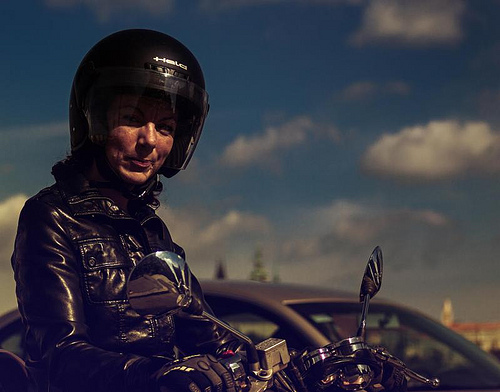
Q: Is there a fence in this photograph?
A: No, there are no fences.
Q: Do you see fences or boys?
A: No, there are no fences or boys.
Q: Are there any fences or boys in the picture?
A: No, there are no fences or boys.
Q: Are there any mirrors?
A: Yes, there is a mirror.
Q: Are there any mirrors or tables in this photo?
A: Yes, there is a mirror.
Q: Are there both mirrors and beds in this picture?
A: No, there is a mirror but no beds.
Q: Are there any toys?
A: No, there are no toys.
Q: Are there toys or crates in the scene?
A: No, there are no toys or crates.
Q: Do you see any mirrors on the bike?
A: Yes, there is a mirror on the bike.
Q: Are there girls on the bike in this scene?
A: No, there is a mirror on the bike.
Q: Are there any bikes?
A: Yes, there is a bike.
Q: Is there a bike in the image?
A: Yes, there is a bike.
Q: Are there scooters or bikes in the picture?
A: Yes, there is a bike.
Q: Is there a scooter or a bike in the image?
A: Yes, there is a bike.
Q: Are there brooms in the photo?
A: No, there are no brooms.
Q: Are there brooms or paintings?
A: No, there are no brooms or paintings.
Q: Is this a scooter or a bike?
A: This is a bike.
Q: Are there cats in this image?
A: No, there are no cats.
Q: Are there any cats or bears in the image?
A: No, there are no cats or bears.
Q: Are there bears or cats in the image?
A: No, there are no cats or bears.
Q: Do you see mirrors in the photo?
A: Yes, there is a mirror.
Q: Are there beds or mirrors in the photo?
A: Yes, there is a mirror.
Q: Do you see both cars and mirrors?
A: Yes, there are both a mirror and a car.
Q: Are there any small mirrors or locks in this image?
A: Yes, there is a small mirror.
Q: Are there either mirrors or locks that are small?
A: Yes, the mirror is small.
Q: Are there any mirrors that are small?
A: Yes, there is a small mirror.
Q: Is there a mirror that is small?
A: Yes, there is a mirror that is small.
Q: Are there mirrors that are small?
A: Yes, there is a mirror that is small.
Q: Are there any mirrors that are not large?
A: Yes, there is a small mirror.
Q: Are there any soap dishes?
A: No, there are no soap dishes.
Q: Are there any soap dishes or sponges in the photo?
A: No, there are no soap dishes or sponges.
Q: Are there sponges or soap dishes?
A: No, there are no soap dishes or sponges.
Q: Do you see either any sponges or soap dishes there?
A: No, there are no soap dishes or sponges.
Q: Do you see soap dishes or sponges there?
A: No, there are no soap dishes or sponges.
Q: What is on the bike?
A: The mirror is on the bike.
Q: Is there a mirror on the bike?
A: Yes, there is a mirror on the bike.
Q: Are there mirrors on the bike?
A: Yes, there is a mirror on the bike.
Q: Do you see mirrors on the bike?
A: Yes, there is a mirror on the bike.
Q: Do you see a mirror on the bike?
A: Yes, there is a mirror on the bike.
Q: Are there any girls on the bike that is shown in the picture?
A: No, there is a mirror on the bike.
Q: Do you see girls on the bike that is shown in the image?
A: No, there is a mirror on the bike.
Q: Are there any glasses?
A: No, there are no glasses.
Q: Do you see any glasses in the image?
A: No, there are no glasses.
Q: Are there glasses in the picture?
A: No, there are no glasses.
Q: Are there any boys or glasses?
A: No, there are no glasses or boys.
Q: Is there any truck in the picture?
A: No, there are no trucks.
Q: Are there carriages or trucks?
A: No, there are no trucks or carriages.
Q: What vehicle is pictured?
A: The vehicle is a car.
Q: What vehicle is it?
A: The vehicle is a car.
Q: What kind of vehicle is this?
A: This is a car.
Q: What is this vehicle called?
A: This is a car.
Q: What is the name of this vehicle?
A: This is a car.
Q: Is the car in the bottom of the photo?
A: Yes, the car is in the bottom of the image.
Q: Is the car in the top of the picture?
A: No, the car is in the bottom of the image.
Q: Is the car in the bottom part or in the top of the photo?
A: The car is in the bottom of the image.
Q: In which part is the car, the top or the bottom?
A: The car is in the bottom of the image.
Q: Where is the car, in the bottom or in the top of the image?
A: The car is in the bottom of the image.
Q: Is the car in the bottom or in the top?
A: The car is in the bottom of the image.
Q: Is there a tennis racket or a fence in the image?
A: No, there are no fences or rackets.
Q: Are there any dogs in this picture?
A: No, there are no dogs.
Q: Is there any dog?
A: No, there are no dogs.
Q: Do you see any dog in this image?
A: No, there are no dogs.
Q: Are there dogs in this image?
A: No, there are no dogs.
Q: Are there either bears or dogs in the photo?
A: No, there are no dogs or bears.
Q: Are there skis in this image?
A: No, there are no skis.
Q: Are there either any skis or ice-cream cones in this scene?
A: No, there are no skis or ice-cream cones.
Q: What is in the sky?
A: The clouds are in the sky.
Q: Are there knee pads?
A: No, there are no knee pads.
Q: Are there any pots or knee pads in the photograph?
A: No, there are no knee pads or pots.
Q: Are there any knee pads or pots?
A: No, there are no knee pads or pots.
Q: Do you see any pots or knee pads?
A: No, there are no knee pads or pots.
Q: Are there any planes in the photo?
A: No, there are no planes.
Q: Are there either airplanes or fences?
A: No, there are no airplanes or fences.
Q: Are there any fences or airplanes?
A: No, there are no airplanes or fences.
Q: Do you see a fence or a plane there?
A: No, there are no airplanes or fences.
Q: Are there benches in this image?
A: No, there are no benches.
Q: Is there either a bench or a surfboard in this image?
A: No, there are no benches or surfboards.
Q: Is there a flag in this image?
A: No, there are no flags.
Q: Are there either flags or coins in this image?
A: No, there are no flags or coins.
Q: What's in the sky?
A: The clouds are in the sky.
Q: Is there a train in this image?
A: No, there are no trains.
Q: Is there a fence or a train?
A: No, there are no trains or fences.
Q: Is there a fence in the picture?
A: No, there are no fences.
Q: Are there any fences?
A: No, there are no fences.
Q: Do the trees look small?
A: Yes, the trees are small.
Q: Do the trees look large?
A: No, the trees are small.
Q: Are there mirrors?
A: Yes, there is a mirror.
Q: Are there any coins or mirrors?
A: Yes, there is a mirror.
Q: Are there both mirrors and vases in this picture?
A: No, there is a mirror but no vases.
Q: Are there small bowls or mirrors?
A: Yes, there is a small mirror.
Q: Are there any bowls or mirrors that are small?
A: Yes, the mirror is small.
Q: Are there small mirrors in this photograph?
A: Yes, there is a small mirror.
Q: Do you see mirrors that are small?
A: Yes, there is a mirror that is small.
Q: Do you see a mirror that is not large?
A: Yes, there is a small mirror.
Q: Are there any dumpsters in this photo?
A: No, there are no dumpsters.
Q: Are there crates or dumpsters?
A: No, there are no dumpsters or crates.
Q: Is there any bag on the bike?
A: No, there is a mirror on the bike.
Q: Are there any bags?
A: No, there are no bags.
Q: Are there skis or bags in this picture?
A: No, there are no bags or skis.